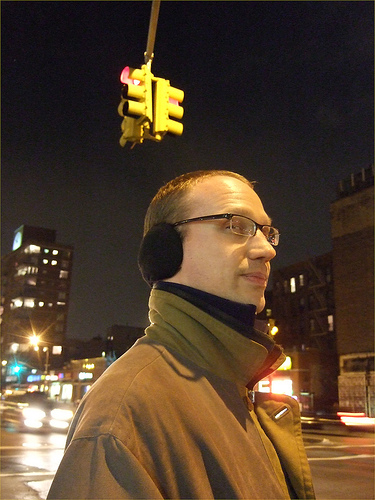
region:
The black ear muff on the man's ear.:
[135, 223, 187, 276]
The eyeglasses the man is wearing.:
[177, 207, 294, 255]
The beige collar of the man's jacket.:
[137, 288, 287, 373]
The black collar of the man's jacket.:
[166, 279, 271, 322]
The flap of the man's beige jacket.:
[246, 390, 297, 429]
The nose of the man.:
[252, 240, 278, 265]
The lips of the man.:
[242, 268, 270, 285]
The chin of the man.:
[250, 294, 268, 312]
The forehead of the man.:
[142, 175, 270, 220]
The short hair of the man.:
[128, 167, 254, 219]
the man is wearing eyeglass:
[154, 204, 305, 279]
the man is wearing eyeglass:
[153, 196, 340, 324]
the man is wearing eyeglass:
[153, 183, 258, 269]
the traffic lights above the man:
[87, 49, 203, 145]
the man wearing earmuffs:
[116, 150, 306, 454]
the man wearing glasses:
[105, 165, 304, 375]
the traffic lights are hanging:
[97, 54, 220, 145]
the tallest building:
[4, 217, 69, 386]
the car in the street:
[0, 382, 63, 446]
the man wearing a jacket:
[36, 176, 328, 495]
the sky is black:
[234, 35, 322, 105]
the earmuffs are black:
[136, 212, 194, 273]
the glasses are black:
[174, 201, 303, 249]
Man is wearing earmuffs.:
[46, 155, 321, 401]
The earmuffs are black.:
[123, 152, 282, 338]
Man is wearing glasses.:
[122, 158, 293, 338]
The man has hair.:
[125, 158, 292, 309]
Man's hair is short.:
[128, 155, 290, 331]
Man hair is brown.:
[127, 166, 290, 319]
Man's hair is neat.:
[107, 150, 302, 331]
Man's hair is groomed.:
[120, 159, 313, 323]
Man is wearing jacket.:
[34, 166, 335, 498]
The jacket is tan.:
[39, 156, 327, 498]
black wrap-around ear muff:
[140, 220, 185, 285]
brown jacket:
[43, 284, 324, 492]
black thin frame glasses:
[170, 212, 283, 245]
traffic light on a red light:
[105, 4, 191, 149]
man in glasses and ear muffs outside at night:
[47, 167, 320, 488]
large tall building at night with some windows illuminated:
[3, 219, 74, 355]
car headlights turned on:
[18, 402, 74, 432]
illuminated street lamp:
[25, 326, 53, 397]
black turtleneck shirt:
[150, 279, 272, 353]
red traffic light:
[117, 62, 149, 119]